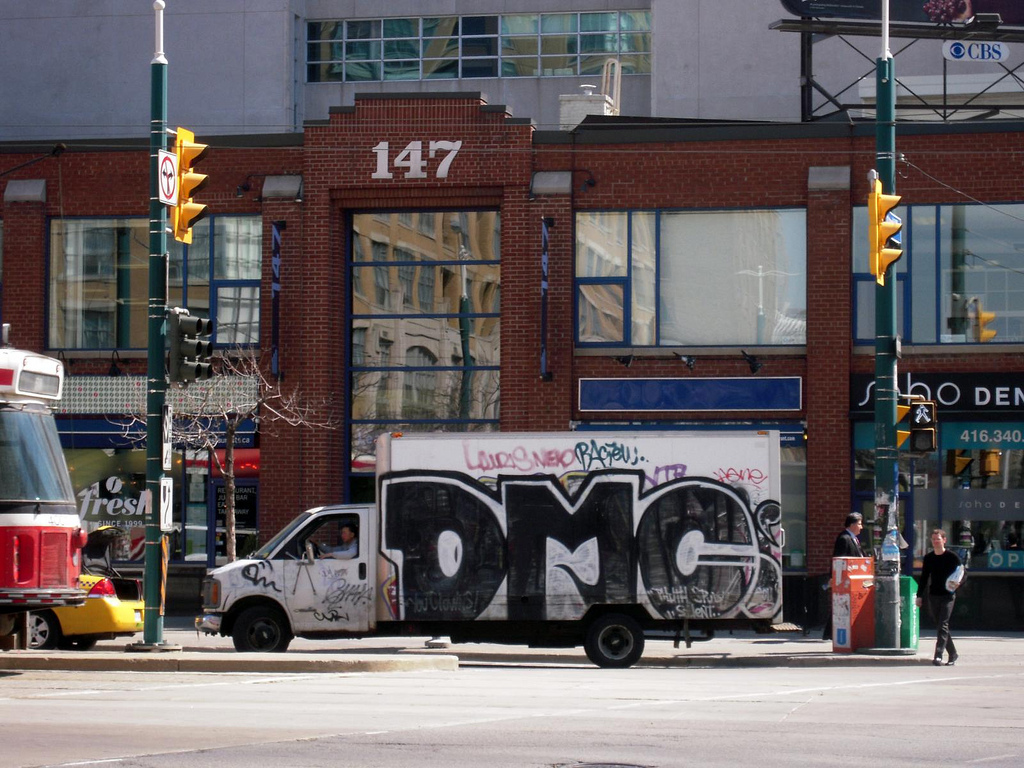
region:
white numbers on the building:
[361, 124, 470, 186]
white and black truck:
[197, 405, 796, 665]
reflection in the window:
[352, 210, 517, 467]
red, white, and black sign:
[159, 152, 186, 209]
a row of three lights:
[880, 183, 906, 282]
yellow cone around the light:
[185, 127, 209, 160]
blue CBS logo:
[936, 35, 1014, 64]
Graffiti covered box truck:
[193, 430, 782, 666]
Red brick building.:
[0, 88, 1022, 630]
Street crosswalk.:
[1, 635, 998, 766]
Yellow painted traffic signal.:
[866, 162, 904, 296]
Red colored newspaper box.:
[826, 554, 880, 653]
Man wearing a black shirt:
[914, 522, 965, 668]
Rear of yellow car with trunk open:
[17, 516, 142, 654]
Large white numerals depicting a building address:
[368, 139, 466, 185]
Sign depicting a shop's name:
[852, 366, 1020, 427]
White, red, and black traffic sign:
[159, 148, 178, 209]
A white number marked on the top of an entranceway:
[372, 138, 462, 180]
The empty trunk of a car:
[119, 583, 135, 593]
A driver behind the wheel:
[321, 521, 359, 557]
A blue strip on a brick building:
[584, 376, 800, 409]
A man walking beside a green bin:
[923, 526, 962, 666]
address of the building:
[363, 133, 465, 188]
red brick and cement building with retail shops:
[2, 89, 1023, 640]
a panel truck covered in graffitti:
[224, 428, 788, 682]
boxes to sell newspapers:
[831, 550, 917, 650]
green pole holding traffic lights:
[141, 73, 164, 655]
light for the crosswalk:
[906, 392, 944, 469]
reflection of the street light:
[442, 216, 485, 419]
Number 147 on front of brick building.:
[364, 138, 462, 180]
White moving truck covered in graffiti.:
[196, 429, 784, 671]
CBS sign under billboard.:
[941, 37, 1009, 63]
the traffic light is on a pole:
[163, 126, 209, 248]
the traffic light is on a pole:
[865, 174, 903, 295]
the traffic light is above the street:
[168, 127, 207, 251]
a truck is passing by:
[212, 424, 794, 674]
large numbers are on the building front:
[372, 132, 465, 189]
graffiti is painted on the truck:
[384, 432, 783, 630]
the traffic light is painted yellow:
[170, 124, 205, 243]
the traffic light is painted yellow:
[863, 178, 899, 289]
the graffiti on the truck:
[194, 430, 801, 665]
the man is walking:
[912, 528, 964, 671]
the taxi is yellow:
[24, 566, 145, 649]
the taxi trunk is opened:
[24, 519, 143, 647]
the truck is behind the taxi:
[32, 427, 801, 675]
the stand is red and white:
[826, 553, 875, 653]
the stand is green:
[876, 574, 921, 647]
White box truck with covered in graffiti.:
[197, 403, 789, 669]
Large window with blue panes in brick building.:
[339, 207, 504, 430]